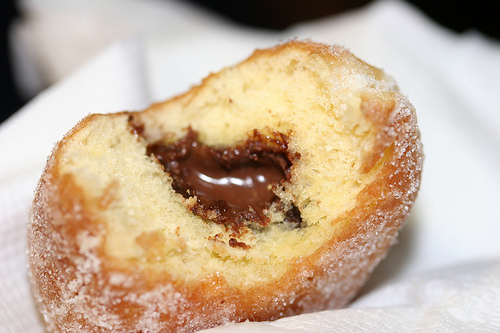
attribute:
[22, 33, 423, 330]
bread — dark, light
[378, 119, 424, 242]
sugar — white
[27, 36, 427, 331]
donut — sugary, fried, golden, sweet, food, dessert, bitten, chocolate filled, sugar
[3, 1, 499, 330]
napkin — white, creased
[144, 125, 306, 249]
filling — chocolate, chocolate cream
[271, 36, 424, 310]
sugar — white, crystaline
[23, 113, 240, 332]
sugar — white, flakey, crystaline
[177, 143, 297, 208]
chocolate filling — in sugary pastry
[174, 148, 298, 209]
chocolate filling — in sugary pastry